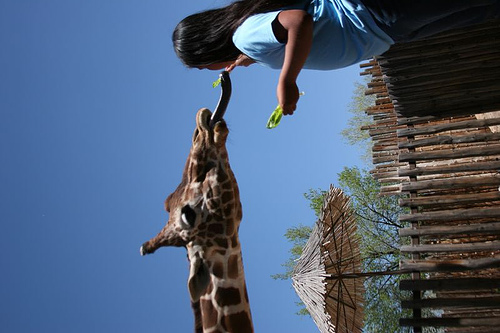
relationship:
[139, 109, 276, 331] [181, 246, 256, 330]
giraffe has neck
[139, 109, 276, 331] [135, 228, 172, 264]
giraffe has horns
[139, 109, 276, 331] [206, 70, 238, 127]
giraffe has tongue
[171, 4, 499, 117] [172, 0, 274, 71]
girl has hair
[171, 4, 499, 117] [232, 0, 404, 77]
girl wearing shirt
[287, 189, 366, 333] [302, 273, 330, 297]
straw made of straw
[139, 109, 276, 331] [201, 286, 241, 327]
giraffe has spots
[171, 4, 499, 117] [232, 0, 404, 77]
girl wears shirt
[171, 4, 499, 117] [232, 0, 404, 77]
girl has shirt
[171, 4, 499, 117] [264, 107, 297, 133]
girl holds lettuce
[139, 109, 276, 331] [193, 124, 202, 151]
giraffe has nose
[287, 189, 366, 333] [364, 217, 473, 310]
straw over area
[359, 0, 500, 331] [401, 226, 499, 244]
area made from wood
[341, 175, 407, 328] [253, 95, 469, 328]
tree in distance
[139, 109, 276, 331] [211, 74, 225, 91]
giraffe eating food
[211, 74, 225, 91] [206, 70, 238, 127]
food on tongue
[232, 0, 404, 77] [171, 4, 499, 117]
shirt on girl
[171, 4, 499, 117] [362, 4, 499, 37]
girl wears pants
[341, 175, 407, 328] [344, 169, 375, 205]
tree has leaves